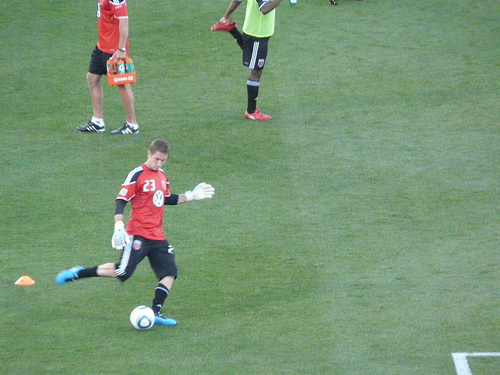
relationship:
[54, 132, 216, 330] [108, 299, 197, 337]
man kicking ball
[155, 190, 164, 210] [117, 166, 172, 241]
logo on shirt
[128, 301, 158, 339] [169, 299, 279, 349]
ball on field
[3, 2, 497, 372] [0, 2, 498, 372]
field of grass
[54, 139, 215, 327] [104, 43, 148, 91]
man carrying beverages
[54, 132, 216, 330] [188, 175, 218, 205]
man wearing gloves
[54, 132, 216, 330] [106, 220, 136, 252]
man wearing gloves